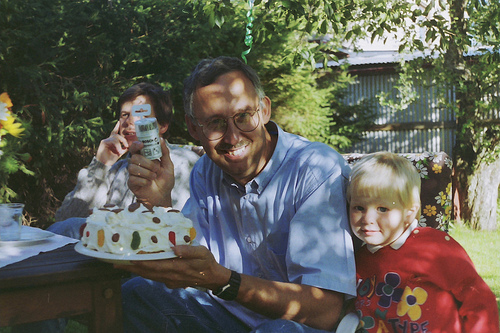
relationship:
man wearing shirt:
[112, 53, 359, 329] [181, 126, 362, 320]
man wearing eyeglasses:
[112, 53, 359, 329] [193, 108, 261, 141]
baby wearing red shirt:
[349, 152, 499, 333] [355, 226, 497, 331]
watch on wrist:
[215, 270, 266, 324] [176, 236, 260, 310]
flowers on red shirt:
[357, 271, 428, 319] [355, 226, 497, 331]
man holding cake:
[112, 53, 359, 329] [74, 200, 198, 260]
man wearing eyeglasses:
[112, 65, 342, 333] [205, 106, 265, 127]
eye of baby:
[378, 196, 390, 215] [344, 140, 484, 327]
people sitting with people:
[33, 51, 496, 331] [51, 70, 212, 250]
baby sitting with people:
[349, 152, 499, 333] [51, 70, 212, 250]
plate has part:
[70, 235, 192, 261] [84, 248, 105, 262]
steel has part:
[319, 45, 499, 155] [386, 106, 395, 120]